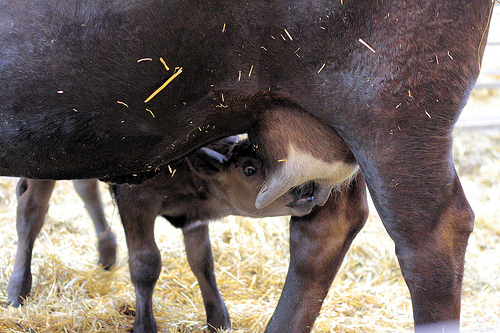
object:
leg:
[4, 177, 56, 309]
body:
[0, 1, 495, 181]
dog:
[6, 115, 308, 325]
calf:
[6, 139, 317, 333]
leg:
[112, 194, 168, 329]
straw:
[135, 65, 203, 113]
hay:
[1, 271, 100, 332]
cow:
[0, 0, 499, 333]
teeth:
[289, 190, 320, 208]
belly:
[4, 21, 240, 183]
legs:
[265, 178, 367, 333]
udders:
[246, 95, 360, 212]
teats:
[252, 172, 332, 211]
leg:
[352, 80, 497, 333]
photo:
[0, 0, 500, 333]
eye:
[240, 162, 258, 177]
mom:
[1, 0, 494, 333]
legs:
[68, 177, 115, 271]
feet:
[260, 108, 474, 331]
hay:
[112, 35, 198, 110]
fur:
[73, 45, 121, 85]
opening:
[14, 179, 34, 199]